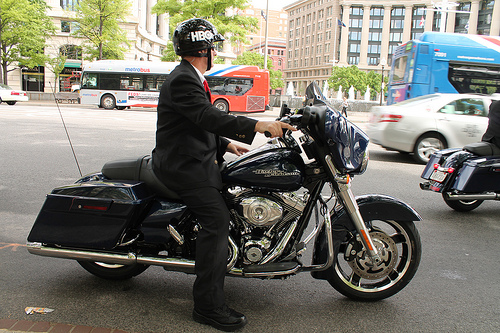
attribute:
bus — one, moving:
[58, 43, 301, 111]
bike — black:
[19, 84, 431, 314]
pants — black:
[180, 186, 232, 305]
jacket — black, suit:
[154, 63, 254, 189]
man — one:
[148, 21, 293, 327]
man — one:
[165, 16, 259, 305]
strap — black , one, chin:
[200, 46, 210, 71]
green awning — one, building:
[59, 59, 84, 69]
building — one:
[39, 0, 96, 100]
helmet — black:
[168, 18, 225, 54]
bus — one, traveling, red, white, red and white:
[77, 60, 269, 115]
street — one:
[2, 95, 499, 331]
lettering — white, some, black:
[190, 29, 213, 41]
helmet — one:
[171, 17, 226, 56]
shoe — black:
[188, 298, 248, 331]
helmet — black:
[151, 12, 228, 60]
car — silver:
[371, 80, 496, 144]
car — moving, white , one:
[3, 75, 30, 107]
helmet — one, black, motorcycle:
[175, 20, 222, 55]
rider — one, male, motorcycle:
[151, 19, 296, 329]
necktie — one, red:
[203, 78, 216, 105]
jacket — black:
[144, 61, 290, 202]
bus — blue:
[383, 22, 499, 134]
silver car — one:
[360, 81, 483, 166]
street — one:
[354, 135, 474, 215]